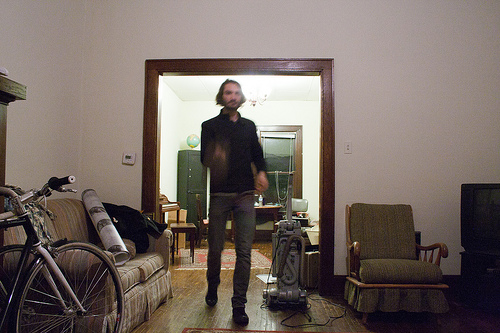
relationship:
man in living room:
[200, 78, 270, 325] [2, 2, 500, 333]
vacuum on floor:
[263, 185, 309, 310] [128, 242, 500, 333]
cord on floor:
[280, 295, 344, 328] [128, 242, 500, 333]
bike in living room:
[0, 174, 127, 333] [2, 2, 500, 333]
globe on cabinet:
[186, 132, 200, 148] [179, 149, 208, 221]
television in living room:
[460, 182, 500, 252] [2, 2, 500, 333]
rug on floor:
[176, 246, 276, 269] [128, 242, 500, 333]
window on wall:
[258, 130, 294, 204] [157, 75, 321, 232]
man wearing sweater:
[200, 78, 270, 325] [201, 109, 266, 197]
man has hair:
[200, 78, 270, 325] [217, 78, 247, 109]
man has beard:
[200, 78, 270, 325] [222, 101, 243, 109]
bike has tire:
[0, 174, 127, 333] [18, 242, 123, 332]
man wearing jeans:
[200, 78, 270, 325] [206, 192, 255, 308]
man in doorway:
[200, 78, 270, 325] [144, 57, 335, 290]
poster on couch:
[80, 188, 132, 265] [2, 198, 171, 332]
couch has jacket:
[2, 198, 171, 332] [103, 201, 168, 253]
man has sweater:
[200, 78, 270, 325] [201, 109, 266, 197]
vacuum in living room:
[263, 185, 309, 310] [2, 2, 500, 333]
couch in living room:
[2, 198, 171, 332] [2, 2, 500, 333]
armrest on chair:
[416, 242, 449, 266] [347, 204, 451, 315]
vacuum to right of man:
[263, 185, 309, 310] [200, 78, 270, 325]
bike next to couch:
[0, 174, 127, 333] [2, 198, 171, 332]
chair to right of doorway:
[347, 204, 451, 315] [144, 57, 335, 290]